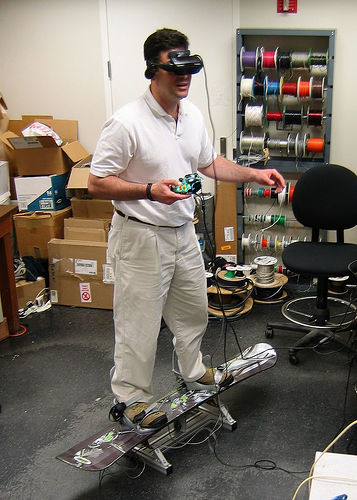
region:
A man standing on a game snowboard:
[57, 27, 275, 477]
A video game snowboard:
[55, 340, 280, 475]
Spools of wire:
[237, 47, 325, 293]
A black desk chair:
[270, 160, 355, 361]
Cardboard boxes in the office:
[0, 96, 113, 318]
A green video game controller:
[167, 170, 203, 201]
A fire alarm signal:
[273, 0, 302, 14]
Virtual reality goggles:
[146, 48, 207, 80]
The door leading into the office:
[98, 1, 236, 164]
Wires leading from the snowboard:
[171, 420, 316, 481]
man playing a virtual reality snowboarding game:
[80, 26, 273, 487]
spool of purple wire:
[238, 49, 258, 67]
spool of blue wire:
[263, 78, 277, 95]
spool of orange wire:
[297, 77, 310, 96]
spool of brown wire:
[312, 77, 322, 98]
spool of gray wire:
[291, 51, 311, 68]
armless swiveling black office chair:
[264, 161, 355, 367]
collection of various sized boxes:
[6, 129, 113, 305]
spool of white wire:
[244, 102, 265, 126]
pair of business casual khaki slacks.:
[108, 213, 211, 391]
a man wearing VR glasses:
[146, 23, 206, 121]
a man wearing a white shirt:
[78, 22, 287, 201]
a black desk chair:
[267, 156, 356, 365]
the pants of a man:
[102, 202, 209, 396]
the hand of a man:
[257, 165, 285, 197]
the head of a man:
[139, 27, 202, 106]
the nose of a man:
[179, 73, 188, 80]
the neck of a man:
[157, 94, 182, 110]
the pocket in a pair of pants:
[115, 224, 128, 261]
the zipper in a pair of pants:
[168, 226, 184, 265]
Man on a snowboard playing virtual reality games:
[83, 25, 279, 433]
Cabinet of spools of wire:
[233, 25, 339, 295]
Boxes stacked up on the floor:
[1, 110, 130, 343]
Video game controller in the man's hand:
[164, 170, 208, 201]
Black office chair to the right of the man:
[262, 164, 354, 368]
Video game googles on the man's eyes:
[141, 43, 206, 82]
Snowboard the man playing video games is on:
[53, 339, 280, 472]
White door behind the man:
[99, 0, 242, 203]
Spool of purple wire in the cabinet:
[237, 43, 261, 75]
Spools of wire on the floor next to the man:
[201, 253, 290, 321]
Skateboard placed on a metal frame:
[54, 339, 282, 479]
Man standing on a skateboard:
[79, 23, 290, 431]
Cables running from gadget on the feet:
[51, 339, 290, 475]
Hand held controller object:
[165, 169, 211, 208]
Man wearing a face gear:
[139, 26, 204, 101]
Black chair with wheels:
[263, 158, 355, 371]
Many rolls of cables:
[204, 33, 331, 318]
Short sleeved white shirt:
[82, 82, 218, 230]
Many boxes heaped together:
[0, 89, 117, 340]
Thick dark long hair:
[135, 23, 190, 67]